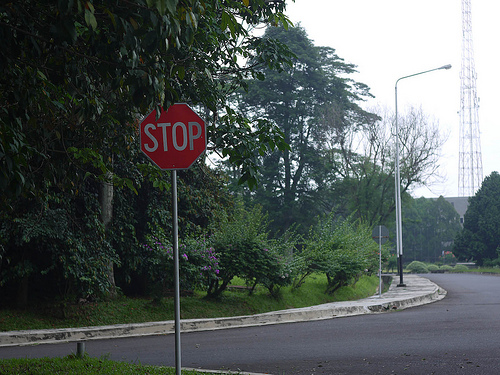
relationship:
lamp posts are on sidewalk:
[382, 223, 410, 278] [303, 305, 328, 319]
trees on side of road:
[0, 46, 109, 153] [273, 343, 310, 353]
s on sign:
[138, 121, 160, 153] [156, 109, 187, 166]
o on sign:
[166, 121, 185, 152] [156, 109, 187, 166]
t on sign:
[150, 123, 169, 155] [156, 109, 187, 166]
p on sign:
[184, 119, 205, 152] [156, 109, 187, 166]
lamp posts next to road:
[394, 78, 404, 284] [273, 272, 496, 374]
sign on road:
[156, 109, 187, 166] [273, 272, 496, 374]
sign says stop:
[156, 109, 187, 166] [135, 121, 198, 149]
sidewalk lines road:
[303, 305, 328, 319] [273, 272, 496, 374]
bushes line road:
[211, 240, 311, 294] [273, 272, 496, 374]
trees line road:
[0, 46, 109, 153] [273, 272, 496, 374]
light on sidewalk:
[389, 221, 404, 276] [303, 305, 328, 319]